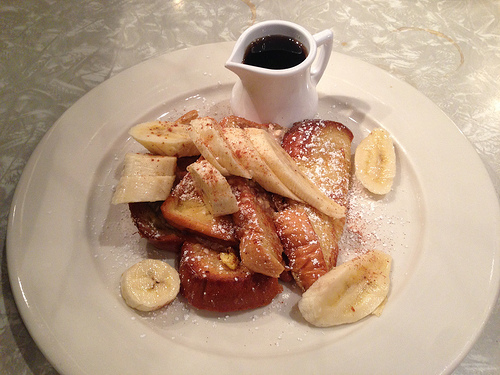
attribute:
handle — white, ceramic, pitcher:
[307, 29, 331, 88]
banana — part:
[291, 239, 398, 335]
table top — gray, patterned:
[408, 10, 482, 93]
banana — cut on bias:
[222, 96, 403, 198]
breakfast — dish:
[105, 107, 408, 331]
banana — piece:
[231, 130, 350, 217]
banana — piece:
[349, 121, 404, 196]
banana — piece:
[292, 242, 393, 328]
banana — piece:
[116, 255, 183, 315]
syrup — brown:
[242, 34, 307, 69]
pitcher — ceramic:
[225, 18, 335, 118]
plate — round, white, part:
[6, 32, 499, 373]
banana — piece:
[110, 175, 174, 202]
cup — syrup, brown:
[224, 19, 333, 129]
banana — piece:
[89, 101, 454, 336]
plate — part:
[450, 210, 486, 279]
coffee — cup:
[250, 35, 305, 67]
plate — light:
[41, 59, 494, 344]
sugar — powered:
[315, 155, 400, 256]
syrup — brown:
[247, 32, 305, 63]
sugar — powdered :
[297, 127, 382, 247]